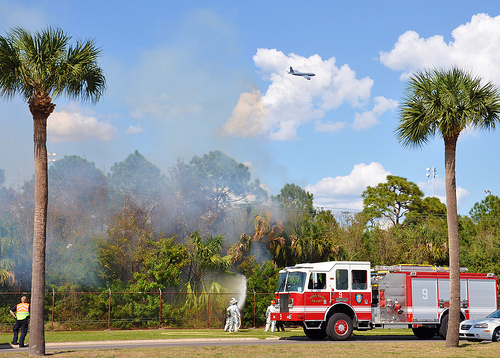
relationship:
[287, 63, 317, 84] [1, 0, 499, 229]
plane in sky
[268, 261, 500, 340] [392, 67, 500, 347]
firetruck next to tree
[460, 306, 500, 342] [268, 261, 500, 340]
car next to firetruck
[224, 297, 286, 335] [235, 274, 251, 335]
people spraying hose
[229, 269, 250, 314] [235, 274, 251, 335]
hose from hose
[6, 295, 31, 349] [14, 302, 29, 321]
man in vest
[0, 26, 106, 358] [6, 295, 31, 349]
tree next to man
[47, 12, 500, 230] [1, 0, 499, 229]
cloud in sky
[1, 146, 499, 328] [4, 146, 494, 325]
trees in background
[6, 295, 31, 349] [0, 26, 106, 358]
man beside tree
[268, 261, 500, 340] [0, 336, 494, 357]
firetruck on street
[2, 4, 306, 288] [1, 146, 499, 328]
smoke coming from trees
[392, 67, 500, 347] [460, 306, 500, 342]
tree by car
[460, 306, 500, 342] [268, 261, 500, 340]
car by firetruck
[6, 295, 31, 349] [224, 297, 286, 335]
man watching people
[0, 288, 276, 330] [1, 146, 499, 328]
fence by trees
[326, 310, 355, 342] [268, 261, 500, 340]
wheel of firetruck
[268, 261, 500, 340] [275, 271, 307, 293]
firetruck has window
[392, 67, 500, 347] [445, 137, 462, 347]
tree has trunk